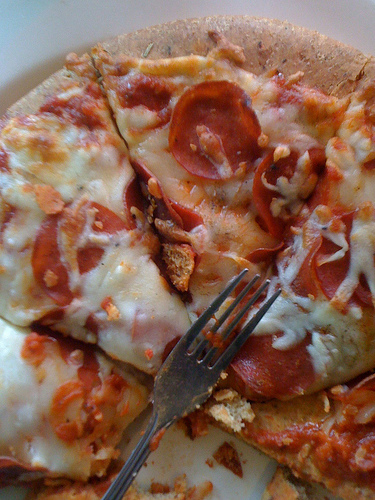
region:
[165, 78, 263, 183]
red circular pepperoni piece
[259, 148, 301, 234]
red circular pepperoni piece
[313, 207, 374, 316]
red circular pepperoni piece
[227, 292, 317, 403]
red circular pepperoni piece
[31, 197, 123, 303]
red circular pepperoni piece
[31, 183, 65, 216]
light brown crust crumb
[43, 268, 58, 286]
light brown crust crumb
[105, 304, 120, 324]
light brown crust crumb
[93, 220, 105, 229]
light brown crust crumb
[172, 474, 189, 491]
light brown crust crumb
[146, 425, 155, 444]
edge of a fork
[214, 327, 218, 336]
tip of a fork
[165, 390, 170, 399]
part of a fork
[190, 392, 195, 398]
part of a spoon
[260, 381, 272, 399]
part of a bread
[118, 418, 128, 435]
edge of a bread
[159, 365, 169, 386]
edge of a fork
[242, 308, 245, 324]
tip of a fork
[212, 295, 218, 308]
side of a fork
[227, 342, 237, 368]
edge of a fork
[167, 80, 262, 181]
Pepperoni is on the pizza.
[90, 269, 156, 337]
Cheese is on the pizza.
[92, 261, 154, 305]
The cheese is melted.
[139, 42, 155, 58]
Seasoning is on the pizza.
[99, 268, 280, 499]
A fork is on the pizza.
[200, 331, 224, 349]
Tomato sauce is on the fork.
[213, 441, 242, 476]
A piece of pepperoni is on the plate.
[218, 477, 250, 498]
The plate is white.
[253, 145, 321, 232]
Melted cheese is on the pepperoni.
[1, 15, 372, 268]
The pizza has been cut into slices.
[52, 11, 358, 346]
triangle shaped slices of pizza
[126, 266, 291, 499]
fork laying on pizza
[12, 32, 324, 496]
pizza on white plate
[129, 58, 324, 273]
pepperoni slices on pizza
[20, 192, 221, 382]
melted cheese and pepperoni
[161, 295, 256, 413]
tomato sauce on fork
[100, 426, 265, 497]
pizza crumbs on plate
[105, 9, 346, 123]
golden brown pizza crust with herbs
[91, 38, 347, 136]
cheese golden brown on crust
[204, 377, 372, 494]
tomato sauce and bottom of pizza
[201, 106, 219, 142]
part of a tomato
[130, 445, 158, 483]
part of a handle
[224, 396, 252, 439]
part of a bread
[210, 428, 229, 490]
part of a crunch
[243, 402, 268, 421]
part of a bread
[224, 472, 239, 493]
part of a surface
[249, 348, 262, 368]
part of a meat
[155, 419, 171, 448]
edge of a fork